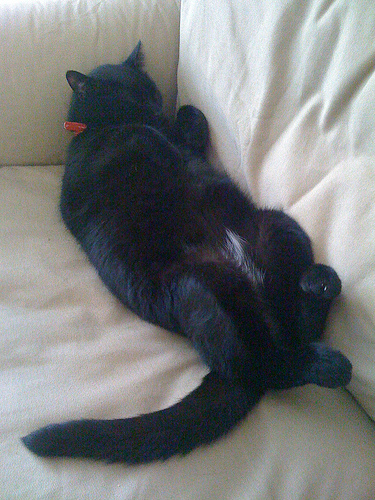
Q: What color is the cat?
A: Black.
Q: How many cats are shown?
A: One.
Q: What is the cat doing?
A: Laying.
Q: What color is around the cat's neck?
A: Red.